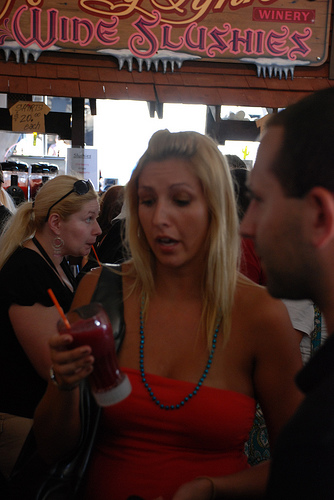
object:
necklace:
[139, 261, 225, 411]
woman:
[31, 127, 309, 498]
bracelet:
[207, 476, 220, 497]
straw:
[46, 286, 74, 326]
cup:
[57, 298, 132, 407]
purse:
[41, 264, 128, 500]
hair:
[121, 127, 243, 351]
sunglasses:
[43, 179, 97, 222]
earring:
[48, 235, 67, 256]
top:
[77, 367, 266, 499]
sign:
[2, 0, 329, 70]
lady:
[0, 175, 103, 493]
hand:
[44, 326, 95, 389]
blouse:
[0, 249, 80, 419]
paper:
[66, 142, 100, 192]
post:
[69, 92, 86, 152]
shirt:
[263, 338, 334, 500]